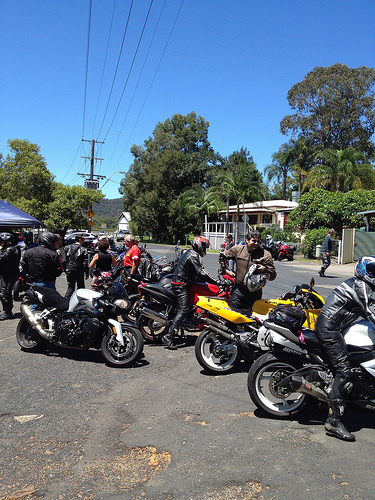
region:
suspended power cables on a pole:
[65, 6, 149, 149]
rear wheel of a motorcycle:
[256, 346, 306, 417]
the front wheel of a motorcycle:
[107, 319, 140, 362]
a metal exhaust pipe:
[203, 313, 234, 336]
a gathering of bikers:
[28, 217, 292, 346]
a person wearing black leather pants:
[317, 310, 355, 401]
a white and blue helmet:
[351, 254, 373, 278]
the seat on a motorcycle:
[212, 295, 256, 315]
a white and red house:
[212, 199, 299, 232]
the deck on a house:
[204, 219, 250, 242]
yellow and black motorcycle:
[186, 274, 329, 370]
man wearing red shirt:
[118, 234, 144, 284]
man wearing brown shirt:
[215, 230, 276, 310]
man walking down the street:
[312, 228, 338, 276]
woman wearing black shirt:
[86, 237, 118, 287]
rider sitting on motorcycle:
[249, 254, 374, 431]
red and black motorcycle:
[138, 260, 237, 346]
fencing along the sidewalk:
[202, 212, 373, 272]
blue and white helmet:
[355, 253, 374, 275]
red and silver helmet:
[194, 233, 209, 259]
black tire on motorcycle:
[99, 320, 142, 366]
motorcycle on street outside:
[16, 279, 144, 366]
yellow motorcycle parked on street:
[193, 286, 323, 374]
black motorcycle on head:
[36, 232, 59, 249]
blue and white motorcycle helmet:
[354, 255, 373, 283]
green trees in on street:
[118, 108, 212, 238]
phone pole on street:
[80, 134, 106, 232]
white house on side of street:
[198, 200, 294, 263]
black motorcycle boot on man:
[325, 398, 355, 440]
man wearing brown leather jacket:
[216, 232, 277, 319]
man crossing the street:
[316, 228, 337, 277]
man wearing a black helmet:
[21, 230, 63, 309]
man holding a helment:
[220, 229, 277, 308]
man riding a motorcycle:
[161, 235, 220, 351]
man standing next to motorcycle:
[218, 230, 278, 309]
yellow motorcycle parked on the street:
[190, 275, 325, 375]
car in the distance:
[114, 230, 132, 242]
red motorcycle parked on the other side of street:
[276, 242, 297, 261]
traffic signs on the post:
[83, 206, 95, 227]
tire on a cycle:
[246, 346, 308, 410]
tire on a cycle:
[192, 327, 231, 372]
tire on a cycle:
[137, 301, 164, 335]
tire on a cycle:
[106, 322, 144, 368]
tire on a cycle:
[11, 315, 41, 345]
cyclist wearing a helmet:
[158, 234, 212, 348]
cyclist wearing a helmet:
[315, 255, 372, 454]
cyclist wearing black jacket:
[304, 246, 368, 441]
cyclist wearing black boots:
[303, 247, 366, 442]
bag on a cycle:
[265, 300, 312, 333]